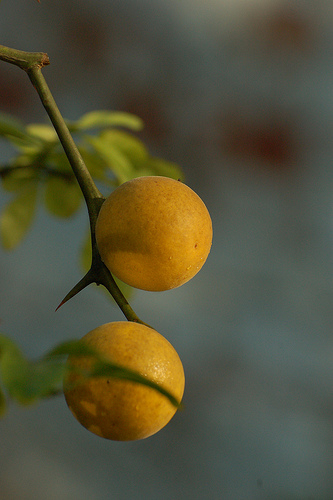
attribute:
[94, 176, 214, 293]
fruit — orange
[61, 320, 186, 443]
fruit — orange, bright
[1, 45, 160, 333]
branch — tree, green, broken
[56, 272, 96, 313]
thorn — sharp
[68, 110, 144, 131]
leaf — green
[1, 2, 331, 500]
sky — vague, blue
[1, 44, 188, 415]
tree — orange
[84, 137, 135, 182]
leaf — green, blurry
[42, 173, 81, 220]
leaf — green, blurry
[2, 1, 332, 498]
distance — blurry